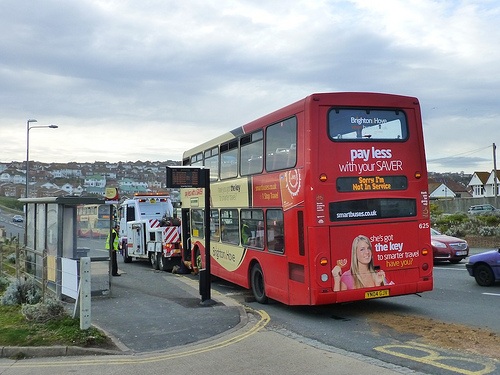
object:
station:
[0, 227, 243, 363]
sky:
[2, 3, 493, 171]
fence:
[427, 196, 500, 218]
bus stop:
[18, 198, 113, 302]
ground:
[443, 155, 465, 183]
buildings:
[1, 160, 499, 204]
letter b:
[370, 343, 495, 374]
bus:
[161, 80, 452, 311]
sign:
[74, 252, 107, 335]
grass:
[1, 240, 115, 355]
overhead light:
[21, 107, 65, 202]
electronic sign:
[163, 165, 216, 305]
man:
[104, 219, 124, 285]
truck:
[110, 189, 190, 274]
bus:
[170, 87, 435, 310]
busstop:
[16, 192, 117, 311]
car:
[430, 225, 470, 264]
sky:
[210, 27, 444, 71]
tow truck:
[110, 186, 181, 275]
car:
[465, 180, 499, 301]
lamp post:
[24, 117, 58, 196]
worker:
[94, 216, 131, 280]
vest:
[103, 231, 126, 251]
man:
[101, 220, 132, 275]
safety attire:
[103, 229, 124, 253]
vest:
[96, 229, 125, 254]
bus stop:
[160, 162, 217, 306]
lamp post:
[16, 110, 69, 210]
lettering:
[338, 140, 401, 168]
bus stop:
[15, 193, 110, 293]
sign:
[166, 165, 216, 306]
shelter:
[15, 195, 113, 297]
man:
[105, 221, 125, 278]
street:
[2, 159, 496, 372]